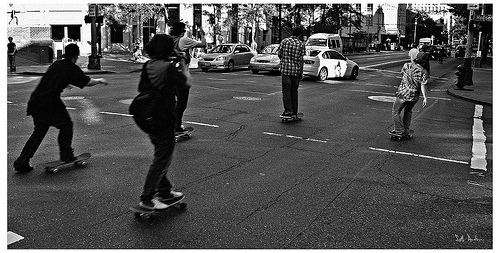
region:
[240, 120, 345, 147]
broken white lines on street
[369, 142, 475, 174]
straight line on the street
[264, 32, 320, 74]
man wearing black and white plaid shirt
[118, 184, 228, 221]
skate board on woman's foot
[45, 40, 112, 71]
black cap on man's head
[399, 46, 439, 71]
white head scarf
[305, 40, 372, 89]
shadow on the car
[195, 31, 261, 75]
large silver automobile on street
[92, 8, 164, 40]
large tree on sidewalk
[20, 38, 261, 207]
people skating in the street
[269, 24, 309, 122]
a person skating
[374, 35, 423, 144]
a person skating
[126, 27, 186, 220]
a person skating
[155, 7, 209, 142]
a person skating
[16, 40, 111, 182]
a person skating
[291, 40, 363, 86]
a vehicle in the street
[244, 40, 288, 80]
a vehicle in the street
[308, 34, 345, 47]
a vehicle in the street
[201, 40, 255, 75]
a vehicle in the street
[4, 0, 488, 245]
a black and white photo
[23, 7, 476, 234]
the picture is black and white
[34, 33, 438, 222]
a group of people riding skateboards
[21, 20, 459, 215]
people riding skateboards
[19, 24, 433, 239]
the people ride skateboards in the road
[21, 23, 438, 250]
the skateboarders are in the road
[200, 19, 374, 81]
cars are also in the road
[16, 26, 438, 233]
the skateboarders are all wearing long pants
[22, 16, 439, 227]
the skateboard riders have no protective gear on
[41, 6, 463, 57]
buildings line the street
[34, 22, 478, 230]
the skateboarders are crossing an intersection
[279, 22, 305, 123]
this is a man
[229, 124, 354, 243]
this is a road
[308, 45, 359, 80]
this is a car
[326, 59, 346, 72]
the car is white in color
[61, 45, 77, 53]
this is a cap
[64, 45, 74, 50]
the cap is black in color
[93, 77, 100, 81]
the man is light skinned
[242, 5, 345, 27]
these are the trees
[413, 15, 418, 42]
this is a pole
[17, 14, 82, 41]
this is a building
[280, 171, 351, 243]
part of a road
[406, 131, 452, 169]
part of a white line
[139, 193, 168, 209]
part of a shoe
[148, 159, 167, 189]
part of a trouser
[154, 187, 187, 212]
edge of a skateboard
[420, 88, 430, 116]
part of a hand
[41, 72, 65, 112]
part of a shirt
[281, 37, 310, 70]
part of a shirt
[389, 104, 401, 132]
part of a trouser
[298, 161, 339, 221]
part of a road